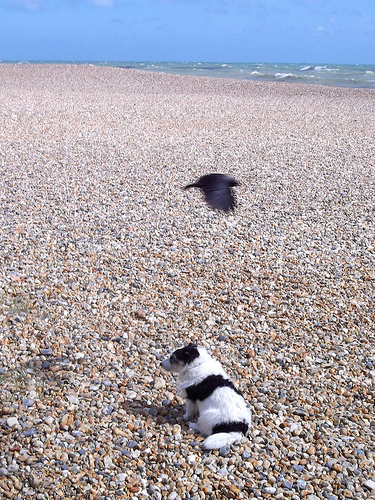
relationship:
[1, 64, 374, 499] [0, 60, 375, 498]
rocks on beach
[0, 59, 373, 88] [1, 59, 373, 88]
ocean in distance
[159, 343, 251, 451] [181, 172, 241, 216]
dog doesnt see bird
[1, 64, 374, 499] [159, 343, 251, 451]
rocks under dog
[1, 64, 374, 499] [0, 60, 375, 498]
rocks at beach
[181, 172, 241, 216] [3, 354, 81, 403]
bird has a shadow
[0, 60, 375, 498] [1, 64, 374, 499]
beach has a lot of rocks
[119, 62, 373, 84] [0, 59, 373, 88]
waves in ocean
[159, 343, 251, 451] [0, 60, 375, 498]
dog at beach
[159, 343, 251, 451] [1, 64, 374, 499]
dog sitting on rocks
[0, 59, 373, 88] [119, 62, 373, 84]
ocean has waves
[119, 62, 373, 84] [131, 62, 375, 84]
waves are color of white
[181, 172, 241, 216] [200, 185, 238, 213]
bird has a wing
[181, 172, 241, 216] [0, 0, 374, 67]
bird in sky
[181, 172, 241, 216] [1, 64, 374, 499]
bird flying above rocks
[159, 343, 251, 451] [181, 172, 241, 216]
dog beneath bird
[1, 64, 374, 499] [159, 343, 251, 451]
rocks are under dog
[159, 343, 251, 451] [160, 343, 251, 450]
dog has color white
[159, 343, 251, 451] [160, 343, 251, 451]
dog has color black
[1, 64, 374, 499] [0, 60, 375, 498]
rocks covering beach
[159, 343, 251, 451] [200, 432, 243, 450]
dog has a tail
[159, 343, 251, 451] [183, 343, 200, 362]
dog has ears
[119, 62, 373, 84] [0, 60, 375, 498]
waves at beach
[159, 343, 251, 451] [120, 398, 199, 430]
dog has a shadow